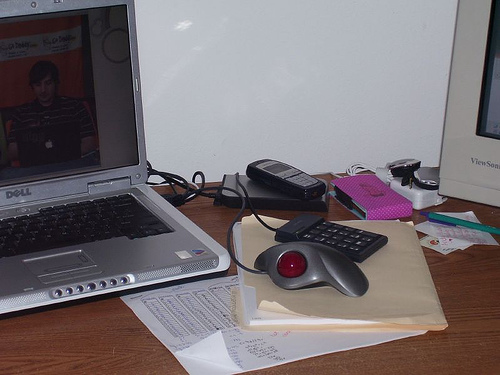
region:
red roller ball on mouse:
[270, 246, 309, 280]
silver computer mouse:
[247, 240, 368, 303]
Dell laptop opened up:
[4, 25, 242, 309]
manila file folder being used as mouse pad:
[230, 203, 450, 345]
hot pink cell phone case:
[328, 162, 415, 231]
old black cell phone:
[247, 149, 325, 204]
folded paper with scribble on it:
[117, 279, 415, 373]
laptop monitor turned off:
[14, 32, 131, 172]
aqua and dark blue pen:
[413, 204, 498, 244]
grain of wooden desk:
[434, 273, 497, 327]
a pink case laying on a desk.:
[330, 167, 415, 222]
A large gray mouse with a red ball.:
[247, 234, 375, 301]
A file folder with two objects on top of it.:
[222, 204, 458, 334]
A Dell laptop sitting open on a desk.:
[0, 12, 186, 337]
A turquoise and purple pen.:
[406, 202, 498, 231]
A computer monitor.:
[426, 0, 498, 241]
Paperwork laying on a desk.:
[135, 266, 354, 373]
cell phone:
[252, 152, 334, 206]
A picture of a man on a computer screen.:
[0, 52, 102, 176]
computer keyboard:
[1, 189, 142, 258]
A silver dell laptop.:
[0, 0, 231, 325]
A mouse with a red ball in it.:
[255, 235, 370, 315]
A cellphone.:
[247, 150, 322, 197]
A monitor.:
[420, 1, 497, 231]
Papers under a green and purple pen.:
[420, 205, 495, 260]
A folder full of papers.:
[226, 215, 441, 335]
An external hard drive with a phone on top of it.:
[202, 155, 332, 210]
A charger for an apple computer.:
[390, 175, 445, 215]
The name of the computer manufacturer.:
[0, 176, 45, 216]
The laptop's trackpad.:
[16, 246, 109, 297]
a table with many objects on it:
[2, 1, 495, 371]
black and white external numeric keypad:
[268, 205, 385, 257]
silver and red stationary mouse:
[245, 235, 368, 300]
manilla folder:
[231, 212, 441, 332]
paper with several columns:
[130, 267, 365, 372]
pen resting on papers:
[417, 202, 493, 242]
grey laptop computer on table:
[1, 0, 228, 320]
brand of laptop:
[0, 180, 55, 212]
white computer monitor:
[428, 5, 498, 206]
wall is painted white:
[211, 11, 442, 133]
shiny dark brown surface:
[28, 325, 108, 357]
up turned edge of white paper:
[175, 324, 252, 374]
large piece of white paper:
[140, 290, 476, 366]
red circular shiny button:
[253, 241, 323, 281]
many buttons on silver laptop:
[45, 271, 142, 303]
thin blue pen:
[426, 203, 498, 243]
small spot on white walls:
[166, 16, 227, 32]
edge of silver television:
[430, 134, 497, 176]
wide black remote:
[278, 206, 400, 261]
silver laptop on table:
[8, 34, 232, 342]